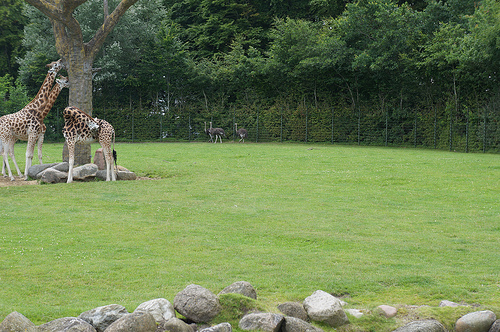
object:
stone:
[455, 306, 498, 331]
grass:
[0, 142, 499, 310]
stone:
[437, 299, 460, 311]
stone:
[301, 290, 347, 322]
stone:
[170, 283, 225, 321]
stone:
[218, 279, 258, 300]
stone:
[134, 295, 177, 332]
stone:
[36, 315, 102, 331]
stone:
[236, 307, 286, 332]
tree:
[427, 4, 492, 151]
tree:
[385, 3, 435, 149]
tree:
[348, 3, 411, 144]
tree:
[282, 11, 339, 141]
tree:
[179, 0, 258, 143]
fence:
[1, 97, 499, 151]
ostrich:
[206, 120, 228, 144]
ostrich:
[229, 121, 252, 144]